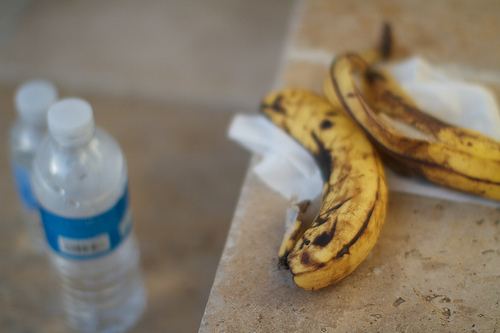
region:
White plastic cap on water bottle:
[49, 97, 99, 144]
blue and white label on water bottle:
[34, 199, 153, 256]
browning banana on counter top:
[274, 81, 382, 287]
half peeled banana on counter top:
[331, 48, 441, 163]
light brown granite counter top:
[400, 231, 485, 331]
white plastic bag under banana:
[244, 119, 310, 198]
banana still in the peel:
[380, 114, 427, 143]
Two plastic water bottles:
[8, 81, 168, 318]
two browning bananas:
[259, 14, 499, 293]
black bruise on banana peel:
[313, 146, 333, 173]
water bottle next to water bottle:
[27, 97, 151, 330]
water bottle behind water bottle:
[7, 80, 63, 264]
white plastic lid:
[44, 96, 96, 148]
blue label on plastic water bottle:
[31, 177, 137, 259]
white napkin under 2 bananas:
[228, 57, 498, 220]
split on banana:
[354, 86, 436, 146]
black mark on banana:
[312, 219, 345, 247]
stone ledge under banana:
[193, 0, 498, 331]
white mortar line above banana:
[281, 47, 337, 65]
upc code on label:
[56, 234, 108, 256]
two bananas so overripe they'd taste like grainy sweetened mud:
[230, 17, 498, 299]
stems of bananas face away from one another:
[270, 20, 400, 294]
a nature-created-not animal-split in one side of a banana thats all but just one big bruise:
[350, 80, 441, 148]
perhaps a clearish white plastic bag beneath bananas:
[220, 48, 498, 238]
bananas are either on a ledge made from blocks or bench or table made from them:
[180, 3, 498, 331]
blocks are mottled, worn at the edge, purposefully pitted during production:
[195, 0, 499, 332]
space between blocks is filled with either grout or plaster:
[280, 46, 499, 96]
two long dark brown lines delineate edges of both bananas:
[293, 46, 498, 299]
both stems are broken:
[271, 17, 401, 279]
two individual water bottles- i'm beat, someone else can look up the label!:
[1, 68, 151, 331]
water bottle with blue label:
[16, 90, 166, 328]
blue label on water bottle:
[25, 174, 140, 277]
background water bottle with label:
[10, 72, 62, 241]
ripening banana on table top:
[259, 75, 397, 332]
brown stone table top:
[185, 4, 498, 331]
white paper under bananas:
[220, 40, 495, 225]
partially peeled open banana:
[315, 31, 457, 183]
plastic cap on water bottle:
[37, 85, 107, 145]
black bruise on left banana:
[297, 120, 340, 195]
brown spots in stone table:
[380, 230, 485, 332]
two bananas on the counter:
[250, 43, 499, 272]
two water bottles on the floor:
[14, 82, 158, 332]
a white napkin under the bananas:
[193, 63, 496, 218]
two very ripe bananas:
[258, 48, 498, 275]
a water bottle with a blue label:
[34, 137, 159, 329]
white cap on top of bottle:
[48, 92, 103, 155]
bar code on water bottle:
[58, 232, 120, 262]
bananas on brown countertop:
[226, 18, 498, 331]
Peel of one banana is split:
[340, 51, 458, 166]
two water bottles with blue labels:
[17, 71, 175, 326]